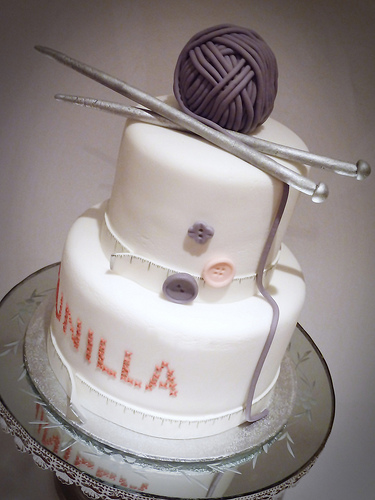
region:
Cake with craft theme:
[20, 23, 329, 445]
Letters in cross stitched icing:
[53, 296, 176, 394]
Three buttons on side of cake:
[159, 221, 238, 300]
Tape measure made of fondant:
[86, 238, 150, 276]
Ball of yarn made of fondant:
[173, 22, 277, 125]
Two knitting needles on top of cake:
[247, 133, 355, 196]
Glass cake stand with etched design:
[288, 351, 320, 459]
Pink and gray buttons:
[161, 223, 231, 301]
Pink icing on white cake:
[80, 344, 147, 376]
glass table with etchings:
[2, 256, 334, 495]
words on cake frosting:
[51, 281, 176, 393]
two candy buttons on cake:
[163, 260, 237, 302]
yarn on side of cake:
[244, 184, 291, 425]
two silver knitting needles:
[34, 43, 369, 198]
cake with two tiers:
[45, 94, 307, 437]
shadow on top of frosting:
[279, 255, 304, 283]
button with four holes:
[206, 257, 233, 286]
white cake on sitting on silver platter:
[18, 23, 349, 471]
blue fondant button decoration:
[160, 264, 202, 309]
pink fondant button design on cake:
[198, 257, 242, 288]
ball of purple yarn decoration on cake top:
[161, 11, 300, 135]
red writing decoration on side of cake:
[42, 288, 201, 399]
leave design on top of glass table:
[277, 426, 298, 457]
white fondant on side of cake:
[191, 322, 246, 395]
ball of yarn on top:
[173, 24, 276, 133]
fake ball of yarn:
[170, 18, 286, 133]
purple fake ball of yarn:
[160, 7, 284, 124]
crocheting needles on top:
[58, 32, 355, 223]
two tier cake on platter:
[26, 24, 347, 460]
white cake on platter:
[8, 97, 318, 463]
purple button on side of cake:
[155, 270, 206, 306]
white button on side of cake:
[202, 257, 237, 288]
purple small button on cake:
[187, 224, 211, 248]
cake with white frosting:
[34, 22, 367, 442]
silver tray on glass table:
[0, 261, 335, 497]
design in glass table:
[281, 351, 319, 458]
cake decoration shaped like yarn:
[172, 22, 279, 137]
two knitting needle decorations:
[34, 44, 369, 200]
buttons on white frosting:
[162, 260, 234, 303]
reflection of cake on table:
[31, 416, 230, 498]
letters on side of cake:
[54, 280, 178, 396]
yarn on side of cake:
[244, 189, 290, 423]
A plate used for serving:
[3, 257, 335, 499]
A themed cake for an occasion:
[20, 20, 370, 467]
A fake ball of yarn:
[173, 23, 279, 422]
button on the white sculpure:
[160, 265, 196, 302]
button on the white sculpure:
[198, 250, 228, 284]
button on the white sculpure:
[184, 217, 209, 241]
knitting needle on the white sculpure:
[33, 41, 329, 204]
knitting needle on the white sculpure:
[53, 90, 372, 180]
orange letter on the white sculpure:
[140, 358, 175, 396]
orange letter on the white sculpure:
[116, 347, 142, 387]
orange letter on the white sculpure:
[93, 334, 117, 376]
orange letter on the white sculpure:
[83, 326, 95, 361]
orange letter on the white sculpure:
[59, 303, 83, 350]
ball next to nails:
[172, 23, 279, 133]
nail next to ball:
[31, 42, 330, 203]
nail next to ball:
[51, 90, 372, 183]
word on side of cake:
[54, 266, 177, 399]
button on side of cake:
[163, 270, 198, 308]